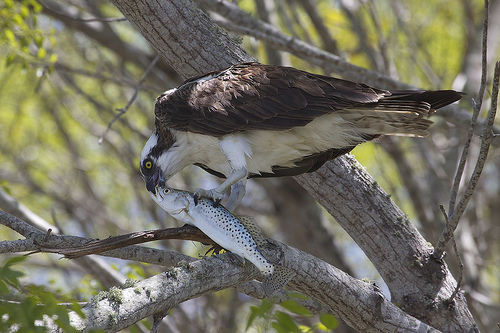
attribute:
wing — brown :
[154, 59, 390, 128]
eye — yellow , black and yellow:
[139, 155, 158, 170]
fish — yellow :
[143, 189, 265, 271]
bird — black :
[137, 58, 462, 212]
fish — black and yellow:
[151, 184, 275, 279]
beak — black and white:
[146, 166, 163, 191]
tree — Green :
[25, 23, 497, 331]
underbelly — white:
[196, 121, 329, 175]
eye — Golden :
[143, 157, 153, 169]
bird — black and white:
[137, 56, 467, 256]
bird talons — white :
[190, 174, 228, 209]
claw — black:
[191, 194, 198, 206]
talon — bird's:
[192, 172, 262, 230]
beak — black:
[142, 163, 162, 195]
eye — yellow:
[142, 157, 152, 169]